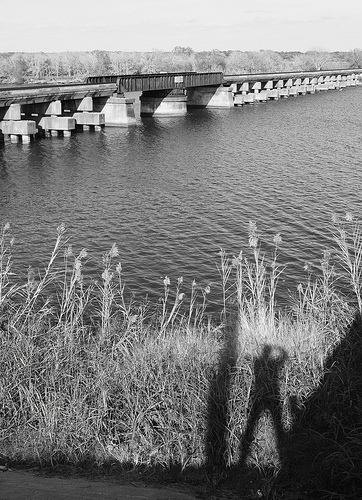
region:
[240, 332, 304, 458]
shadow of person on ground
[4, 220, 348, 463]
the grass is very high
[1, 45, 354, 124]
a bridge is in middle of water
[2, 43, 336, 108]
many trees are in the background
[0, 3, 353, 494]
the picture is in black and white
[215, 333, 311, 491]
the shadow is black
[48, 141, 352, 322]
the water has waves in it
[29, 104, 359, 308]
the waves are calm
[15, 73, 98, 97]
cars are in the background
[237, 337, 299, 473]
Shadow of a man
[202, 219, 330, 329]
Tall grass growing by water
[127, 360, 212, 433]
A small patch of grass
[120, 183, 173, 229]
A small body of water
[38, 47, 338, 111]
A long bridge over water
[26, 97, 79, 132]
Support pylon for bridge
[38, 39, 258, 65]
A line of trees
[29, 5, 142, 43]
A white clouded sky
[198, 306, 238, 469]
The shadow of a tree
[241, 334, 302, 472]
A man taking a picture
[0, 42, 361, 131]
a bridge over water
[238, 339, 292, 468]
a man's shadow in the tall grass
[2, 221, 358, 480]
a patch of tall grass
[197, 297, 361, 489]
a group of cast shadows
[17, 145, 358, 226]
wind swept water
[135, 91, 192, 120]
a bridge pillar in the water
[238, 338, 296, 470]
the photographer's shadow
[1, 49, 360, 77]
trees in the distance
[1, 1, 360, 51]
a cloudy, hazy sky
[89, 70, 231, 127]
a water passable section of the bridge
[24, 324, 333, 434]
plants next to the road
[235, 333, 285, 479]
shadow of cameraman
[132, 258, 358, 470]
shadow of car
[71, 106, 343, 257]
a river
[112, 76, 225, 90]
walled off section of bridge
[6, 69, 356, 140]
a long bridge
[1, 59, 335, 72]
wooded area on the other side of the bridge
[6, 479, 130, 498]
a small portion of road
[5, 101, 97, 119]
large bridge supports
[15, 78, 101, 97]
railroad tracks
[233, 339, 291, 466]
The shadow of the photographer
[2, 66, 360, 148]
The bridge over the water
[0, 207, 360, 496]
The weeds on the near bank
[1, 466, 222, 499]
The dirt walk way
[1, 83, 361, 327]
The body of water the bridge is over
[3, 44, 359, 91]
The trees in the background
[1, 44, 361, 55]
The horizon line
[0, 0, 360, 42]
The empty white sky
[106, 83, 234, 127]
The three large bridge supports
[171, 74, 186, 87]
The white sign on the bridge